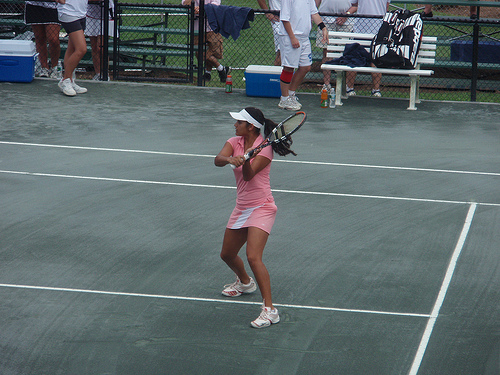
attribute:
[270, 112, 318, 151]
racket — black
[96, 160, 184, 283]
court — green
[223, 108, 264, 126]
visor — white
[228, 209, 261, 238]
skirt — pink, tennis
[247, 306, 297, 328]
sneakers — white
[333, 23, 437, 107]
bench — white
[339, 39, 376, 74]
bag — black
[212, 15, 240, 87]
fence — chain-link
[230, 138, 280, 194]
shirt — pink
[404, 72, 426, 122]
legs — white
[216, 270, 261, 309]
shoes — white